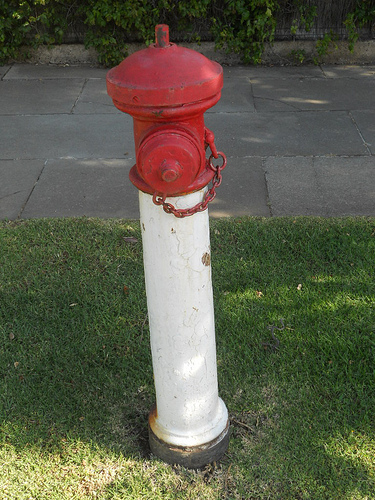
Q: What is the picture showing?
A: It is showing a sidewalk.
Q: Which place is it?
A: It is a sidewalk.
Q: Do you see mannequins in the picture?
A: No, there are no mannequins.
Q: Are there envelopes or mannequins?
A: No, there are no mannequins or envelopes.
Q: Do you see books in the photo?
A: No, there are no books.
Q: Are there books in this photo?
A: No, there are no books.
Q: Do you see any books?
A: No, there are no books.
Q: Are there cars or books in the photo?
A: No, there are no books or cars.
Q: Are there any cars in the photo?
A: No, there are no cars.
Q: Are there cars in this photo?
A: No, there are no cars.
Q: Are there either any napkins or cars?
A: No, there are no cars or napkins.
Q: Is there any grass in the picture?
A: Yes, there is grass.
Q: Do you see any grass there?
A: Yes, there is grass.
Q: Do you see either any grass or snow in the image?
A: Yes, there is grass.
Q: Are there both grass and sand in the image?
A: No, there is grass but no sand.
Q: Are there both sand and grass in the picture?
A: No, there is grass but no sand.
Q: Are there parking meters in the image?
A: No, there are no parking meters.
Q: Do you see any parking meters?
A: No, there are no parking meters.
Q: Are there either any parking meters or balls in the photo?
A: No, there are no parking meters or balls.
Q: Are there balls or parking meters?
A: No, there are no parking meters or balls.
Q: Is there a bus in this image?
A: No, there are no buses.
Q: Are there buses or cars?
A: No, there are no buses or cars.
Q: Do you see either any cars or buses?
A: No, there are no buses or cars.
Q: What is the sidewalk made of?
A: The sidewalk is made of concrete.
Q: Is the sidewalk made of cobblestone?
A: No, the sidewalk is made of concrete.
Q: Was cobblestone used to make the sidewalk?
A: No, the sidewalk is made of concrete.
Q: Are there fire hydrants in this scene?
A: Yes, there is a fire hydrant.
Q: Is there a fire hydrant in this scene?
A: Yes, there is a fire hydrant.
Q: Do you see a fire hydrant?
A: Yes, there is a fire hydrant.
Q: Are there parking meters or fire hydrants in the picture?
A: Yes, there is a fire hydrant.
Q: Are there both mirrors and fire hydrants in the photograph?
A: No, there is a fire hydrant but no mirrors.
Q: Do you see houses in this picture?
A: No, there are no houses.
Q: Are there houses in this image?
A: No, there are no houses.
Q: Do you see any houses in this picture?
A: No, there are no houses.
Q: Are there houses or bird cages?
A: No, there are no houses or bird cages.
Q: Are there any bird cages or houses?
A: No, there are no houses or bird cages.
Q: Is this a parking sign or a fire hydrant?
A: This is a fire hydrant.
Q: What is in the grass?
A: The fire hydrant is in the grass.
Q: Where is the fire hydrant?
A: The fire hydrant is in the grass.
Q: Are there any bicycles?
A: No, there are no bicycles.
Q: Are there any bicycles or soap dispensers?
A: No, there are no bicycles or soap dispensers.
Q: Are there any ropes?
A: No, there are no ropes.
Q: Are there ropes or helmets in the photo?
A: No, there are no ropes or helmets.